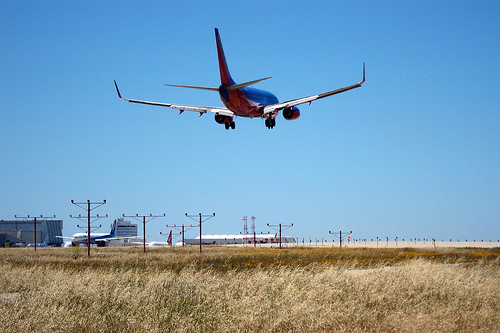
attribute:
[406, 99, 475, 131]
clouds — white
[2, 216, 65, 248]
building — large gray 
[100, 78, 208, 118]
wing — white, Left blue 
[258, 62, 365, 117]
wing — Right blue, white 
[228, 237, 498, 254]
fence — white 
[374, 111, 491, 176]
blue sky — clear blue.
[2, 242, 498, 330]
grass — Dried 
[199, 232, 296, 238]
clouds — white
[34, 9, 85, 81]
sky —  blue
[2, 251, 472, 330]
grass — dying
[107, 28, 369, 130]
plane —  BLUE ,  WHITE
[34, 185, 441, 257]
posts — tall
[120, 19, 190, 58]
clouds — white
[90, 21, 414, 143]
plane — blue and red.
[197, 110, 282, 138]
landing gear — down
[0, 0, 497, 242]
sky — blue, BRIGHT BLUE 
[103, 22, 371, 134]
airplane — white 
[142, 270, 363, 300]
area — GRASSY, TAN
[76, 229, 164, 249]
plane — white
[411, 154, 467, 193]
clouds — white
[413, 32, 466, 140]
sky —  blue